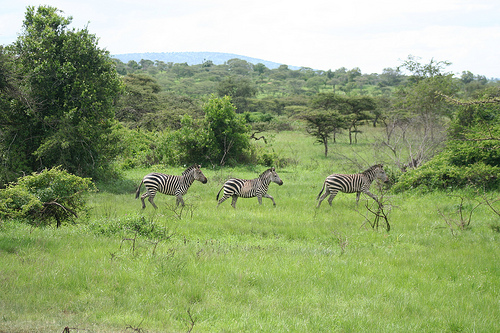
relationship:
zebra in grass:
[135, 163, 208, 213] [2, 129, 500, 333]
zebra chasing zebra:
[135, 163, 208, 213] [314, 163, 390, 211]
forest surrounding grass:
[0, 5, 500, 117] [2, 129, 500, 333]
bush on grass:
[1, 164, 100, 228] [2, 129, 500, 333]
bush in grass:
[1, 164, 100, 228] [2, 129, 500, 333]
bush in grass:
[176, 94, 273, 169] [2, 129, 500, 333]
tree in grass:
[303, 110, 351, 157] [2, 129, 500, 333]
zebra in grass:
[215, 167, 283, 208] [2, 129, 500, 333]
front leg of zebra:
[177, 188, 185, 205] [135, 163, 208, 213]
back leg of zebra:
[141, 189, 154, 210] [135, 163, 208, 213]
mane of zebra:
[183, 165, 199, 175] [135, 163, 208, 213]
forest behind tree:
[0, 5, 500, 117] [303, 110, 351, 157]